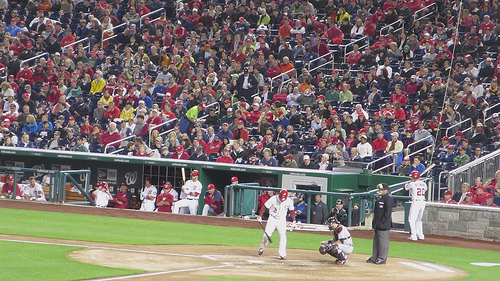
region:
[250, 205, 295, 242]
the clothes are white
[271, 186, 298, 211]
the helmet is red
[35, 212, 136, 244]
the grass is green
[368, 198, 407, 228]
the jacket is black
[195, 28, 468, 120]
there are spectators on the stands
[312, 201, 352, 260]
the man is squatting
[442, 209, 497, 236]
the walls are made of bricks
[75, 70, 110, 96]
the man has yellow shirt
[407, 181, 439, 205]
theere is number 20 on the shirt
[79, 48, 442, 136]
the major color is red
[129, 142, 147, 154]
a person is sitting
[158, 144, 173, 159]
a person is sitting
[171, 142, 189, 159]
a person is sitting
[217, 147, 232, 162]
a person is sitting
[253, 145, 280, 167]
a person is sitting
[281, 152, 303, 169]
a person is sitting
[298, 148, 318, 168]
a person is sitting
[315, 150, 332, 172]
a person is sitting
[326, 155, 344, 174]
a person is sitting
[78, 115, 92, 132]
a person is sitting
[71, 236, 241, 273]
brown circular infield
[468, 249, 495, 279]
white spot on the grass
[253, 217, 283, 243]
black bat in the man's hand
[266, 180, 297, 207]
shiny red helmet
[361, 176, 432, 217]
black and white helmet on man's face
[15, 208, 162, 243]
green grass on the field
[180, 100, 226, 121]
man wearing green shirt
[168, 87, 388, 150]
spectators in the stands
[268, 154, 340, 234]
large white door in the dugout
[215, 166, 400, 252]
green chain link fence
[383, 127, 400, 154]
a person is sitting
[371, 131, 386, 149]
a person is sitting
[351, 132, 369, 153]
a person is sitting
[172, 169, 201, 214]
a person is sitting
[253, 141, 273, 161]
a person is sitting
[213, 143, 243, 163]
a person is sitting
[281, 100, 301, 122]
a person is sitting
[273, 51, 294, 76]
a person is sitting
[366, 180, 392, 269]
umpire waits for the pitch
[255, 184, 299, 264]
batter digs into the dirt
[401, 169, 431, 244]
player is waiting on deck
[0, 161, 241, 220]
teammates are waiting in the dugout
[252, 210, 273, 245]
batter holds bat in right hand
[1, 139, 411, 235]
green dugout area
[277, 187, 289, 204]
red helmet on batter's head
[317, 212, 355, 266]
catcher crouched behind the plate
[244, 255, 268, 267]
white home plate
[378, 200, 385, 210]
white writing on umpire's coat